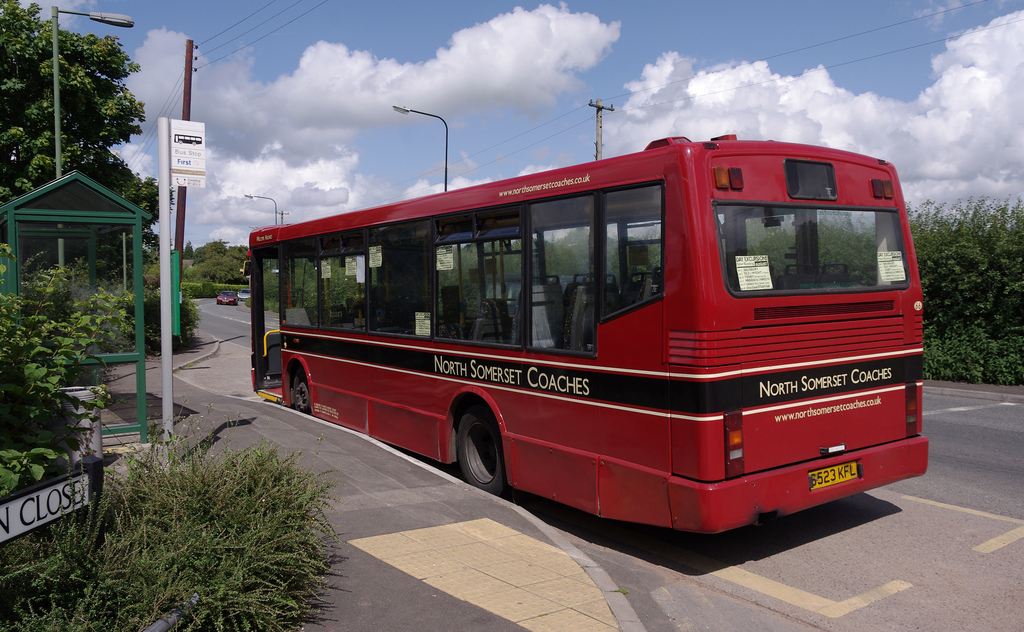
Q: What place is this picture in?
A: It is at the pavement.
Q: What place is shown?
A: It is a pavement.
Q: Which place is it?
A: It is a pavement.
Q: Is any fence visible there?
A: No, there are no fences.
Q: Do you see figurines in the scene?
A: No, there are no figurines.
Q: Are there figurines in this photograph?
A: No, there are no figurines.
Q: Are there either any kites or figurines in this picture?
A: No, there are no figurines or kites.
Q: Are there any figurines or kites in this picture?
A: No, there are no figurines or kites.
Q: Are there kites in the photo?
A: No, there are no kites.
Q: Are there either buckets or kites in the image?
A: No, there are no kites or buckets.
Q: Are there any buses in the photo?
A: Yes, there is a bus.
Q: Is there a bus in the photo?
A: Yes, there is a bus.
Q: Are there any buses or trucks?
A: Yes, there is a bus.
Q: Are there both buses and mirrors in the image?
A: No, there is a bus but no mirrors.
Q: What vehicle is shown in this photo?
A: The vehicle is a bus.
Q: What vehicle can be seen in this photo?
A: The vehicle is a bus.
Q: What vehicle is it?
A: The vehicle is a bus.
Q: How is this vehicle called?
A: This is a bus.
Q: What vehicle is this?
A: This is a bus.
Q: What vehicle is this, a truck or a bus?
A: This is a bus.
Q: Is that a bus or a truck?
A: That is a bus.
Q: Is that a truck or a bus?
A: That is a bus.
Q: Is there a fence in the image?
A: No, there are no fences.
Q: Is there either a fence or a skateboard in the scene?
A: No, there are no fences or skateboards.